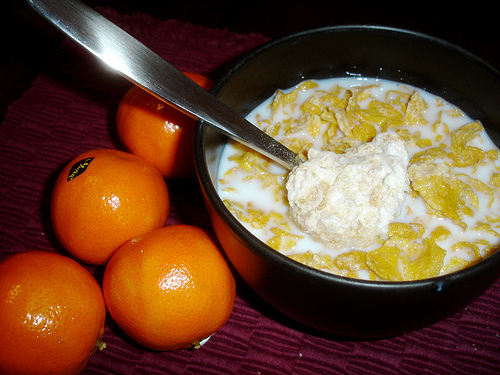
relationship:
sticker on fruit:
[66, 156, 95, 183] [0, 248, 104, 375]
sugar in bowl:
[285, 130, 411, 247] [192, 22, 500, 342]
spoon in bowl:
[27, 0, 304, 173] [192, 22, 500, 342]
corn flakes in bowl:
[218, 79, 499, 283] [192, 22, 500, 342]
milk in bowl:
[216, 72, 500, 282] [192, 22, 500, 342]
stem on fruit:
[95, 337, 106, 352] [2, 249, 107, 374]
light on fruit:
[157, 260, 198, 295] [0, 248, 104, 375]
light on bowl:
[258, 242, 438, 291] [192, 22, 500, 342]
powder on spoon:
[258, 129, 300, 170] [27, 0, 304, 173]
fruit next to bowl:
[116, 70, 216, 178] [192, 22, 500, 342]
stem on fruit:
[190, 339, 201, 351] [0, 248, 104, 375]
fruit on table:
[0, 248, 104, 375] [0, 0, 500, 119]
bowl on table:
[192, 22, 500, 342] [0, 0, 500, 119]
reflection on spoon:
[88, 29, 143, 85] [27, 0, 304, 173]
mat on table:
[0, 5, 499, 374] [0, 0, 500, 119]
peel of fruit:
[101, 222, 237, 352] [0, 248, 104, 375]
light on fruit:
[103, 193, 122, 211] [0, 248, 104, 375]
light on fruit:
[162, 119, 181, 135] [116, 70, 216, 178]